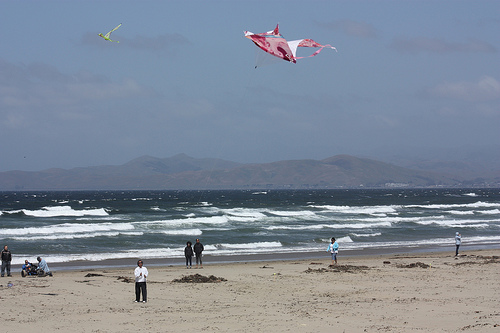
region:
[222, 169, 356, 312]
the beach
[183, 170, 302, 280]
the beach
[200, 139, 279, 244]
the beach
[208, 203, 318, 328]
the beach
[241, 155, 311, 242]
the beach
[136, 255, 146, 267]
the head of a man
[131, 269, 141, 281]
the arm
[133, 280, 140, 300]
the leg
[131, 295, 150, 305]
a pair of shoes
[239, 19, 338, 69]
a kite in the sky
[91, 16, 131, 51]
a green kite in the sky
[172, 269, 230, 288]
a pile of dirt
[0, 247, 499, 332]
brown sand on the beach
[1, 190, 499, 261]
a large body of water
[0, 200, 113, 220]
a foaming white wave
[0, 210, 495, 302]
people on the beach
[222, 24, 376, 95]
a white and red kite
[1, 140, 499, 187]
a chain of small mountains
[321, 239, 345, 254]
person with a baby blue jacket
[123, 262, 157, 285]
man wearing a white long sleeve shit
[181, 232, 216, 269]
two people wearing black on the beach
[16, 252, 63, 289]
two people sitting on the sand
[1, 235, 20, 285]
man standing by the ocean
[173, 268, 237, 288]
wet sand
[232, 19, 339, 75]
big white and pink kite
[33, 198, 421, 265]
White ripples in water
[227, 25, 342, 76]
Red and white kite in sky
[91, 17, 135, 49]
Lime green kite in sky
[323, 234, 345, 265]
Woman wearing blue jacket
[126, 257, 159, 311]
Man standing in the sand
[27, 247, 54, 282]
Man kneeling in the sand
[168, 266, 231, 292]
Piles on sand on the beach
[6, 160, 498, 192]
Mountains in the background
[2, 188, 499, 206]
Ocean water is dark blue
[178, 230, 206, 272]
Couple standing by water